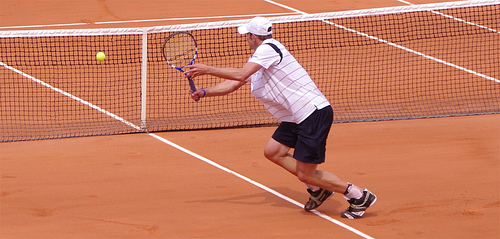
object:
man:
[180, 14, 379, 221]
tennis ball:
[96, 50, 106, 63]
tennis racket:
[159, 31, 201, 104]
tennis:
[79, 12, 305, 124]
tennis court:
[2, 1, 500, 236]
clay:
[32, 180, 133, 225]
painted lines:
[162, 139, 252, 180]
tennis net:
[1, 1, 498, 128]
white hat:
[235, 15, 276, 39]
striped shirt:
[248, 38, 331, 125]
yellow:
[98, 52, 102, 58]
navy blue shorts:
[268, 104, 333, 164]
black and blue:
[171, 56, 200, 86]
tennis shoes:
[338, 187, 379, 220]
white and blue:
[350, 201, 369, 220]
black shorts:
[291, 104, 335, 165]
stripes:
[263, 41, 283, 65]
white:
[249, 178, 264, 187]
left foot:
[338, 188, 378, 221]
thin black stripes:
[281, 74, 308, 101]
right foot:
[301, 182, 335, 213]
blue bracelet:
[198, 88, 207, 98]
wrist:
[196, 88, 208, 101]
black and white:
[364, 187, 379, 204]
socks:
[344, 184, 364, 204]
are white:
[222, 165, 250, 182]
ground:
[367, 104, 455, 132]